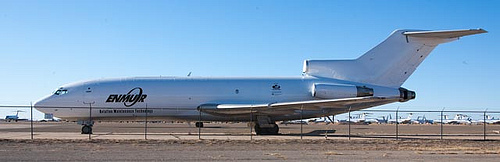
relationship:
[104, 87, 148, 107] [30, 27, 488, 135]
logo in airplane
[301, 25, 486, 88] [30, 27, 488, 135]
white tail in airplane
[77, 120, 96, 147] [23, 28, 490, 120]
landing gear in plane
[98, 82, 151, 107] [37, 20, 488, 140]
logo on side of plane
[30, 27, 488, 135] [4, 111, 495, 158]
airplane parked on tarmac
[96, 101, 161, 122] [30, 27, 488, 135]
letter on side of airplane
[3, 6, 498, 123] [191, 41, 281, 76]
sky has clouds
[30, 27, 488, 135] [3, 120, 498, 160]
airplane on ground